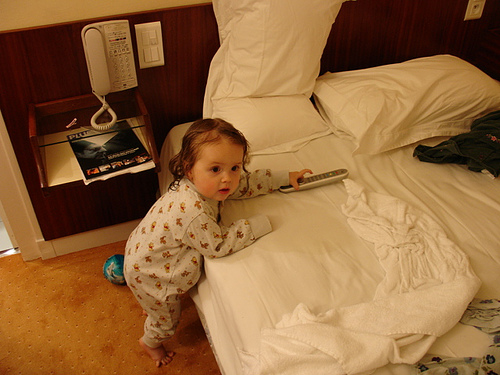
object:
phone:
[81, 19, 140, 132]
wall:
[1, 1, 499, 260]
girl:
[122, 118, 315, 366]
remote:
[279, 168, 350, 195]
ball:
[103, 254, 127, 285]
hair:
[168, 116, 250, 199]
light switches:
[150, 47, 161, 63]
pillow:
[202, 3, 345, 157]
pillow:
[310, 54, 499, 155]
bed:
[150, 53, 500, 373]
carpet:
[0, 238, 224, 374]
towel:
[260, 179, 483, 374]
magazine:
[66, 118, 155, 185]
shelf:
[21, 85, 161, 194]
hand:
[288, 167, 314, 189]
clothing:
[413, 108, 500, 177]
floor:
[0, 248, 20, 258]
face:
[195, 144, 244, 202]